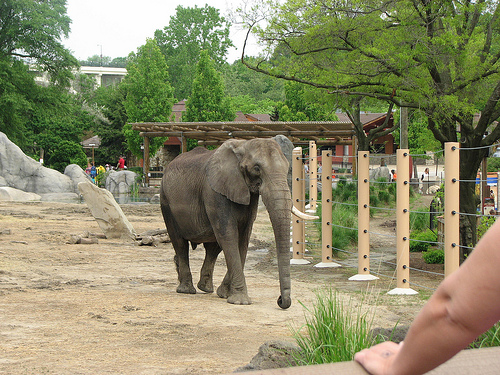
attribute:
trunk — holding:
[246, 177, 324, 327]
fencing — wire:
[292, 139, 480, 291]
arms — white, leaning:
[388, 213, 498, 364]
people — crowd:
[63, 139, 183, 205]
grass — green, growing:
[278, 290, 398, 368]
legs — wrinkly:
[164, 219, 275, 303]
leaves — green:
[207, 20, 441, 123]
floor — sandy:
[33, 262, 294, 362]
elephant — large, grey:
[174, 128, 356, 370]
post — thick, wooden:
[338, 139, 383, 295]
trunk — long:
[235, 178, 319, 281]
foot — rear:
[163, 253, 214, 307]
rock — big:
[44, 163, 139, 242]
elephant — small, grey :
[159, 134, 294, 308]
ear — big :
[207, 138, 252, 206]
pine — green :
[120, 38, 171, 156]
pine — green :
[180, 49, 235, 120]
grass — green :
[293, 287, 376, 367]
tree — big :
[236, 0, 498, 264]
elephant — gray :
[158, 133, 320, 310]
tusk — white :
[291, 204, 321, 221]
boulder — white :
[77, 179, 135, 239]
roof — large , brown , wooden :
[129, 119, 358, 139]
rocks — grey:
[1, 123, 151, 239]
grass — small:
[270, 268, 390, 373]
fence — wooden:
[437, 338, 488, 368]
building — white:
[32, 52, 170, 131]